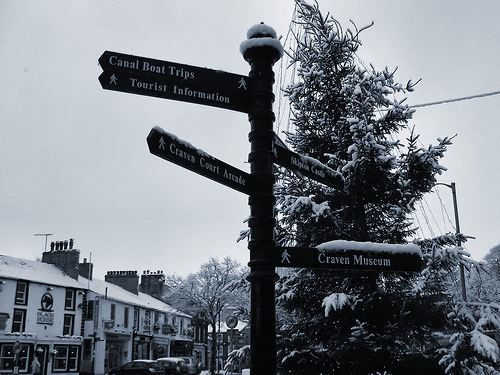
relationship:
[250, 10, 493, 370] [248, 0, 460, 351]
snow on tree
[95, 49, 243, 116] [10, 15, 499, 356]
sign on corner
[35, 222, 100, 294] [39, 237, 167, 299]
chimney on chimneys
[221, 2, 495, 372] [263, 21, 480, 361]
snow on tree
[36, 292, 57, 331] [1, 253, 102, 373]
black sign on building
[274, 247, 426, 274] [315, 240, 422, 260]
sign covered in snow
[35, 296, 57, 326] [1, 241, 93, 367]
black sign on building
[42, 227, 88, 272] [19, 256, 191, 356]
chimney on building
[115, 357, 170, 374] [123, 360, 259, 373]
car parked on street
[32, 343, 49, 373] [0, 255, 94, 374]
door in building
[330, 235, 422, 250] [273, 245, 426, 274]
snow on sign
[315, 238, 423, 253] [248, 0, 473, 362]
snow on tree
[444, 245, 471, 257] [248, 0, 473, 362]
snow on tree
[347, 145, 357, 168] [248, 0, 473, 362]
snow on tree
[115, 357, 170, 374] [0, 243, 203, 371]
car are parked in front of building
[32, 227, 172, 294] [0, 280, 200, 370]
chimneys on top of building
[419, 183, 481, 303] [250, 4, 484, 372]
lightpole near tree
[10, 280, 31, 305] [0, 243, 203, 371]
window on building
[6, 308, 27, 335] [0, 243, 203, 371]
window on building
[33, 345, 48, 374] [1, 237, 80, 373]
door to building